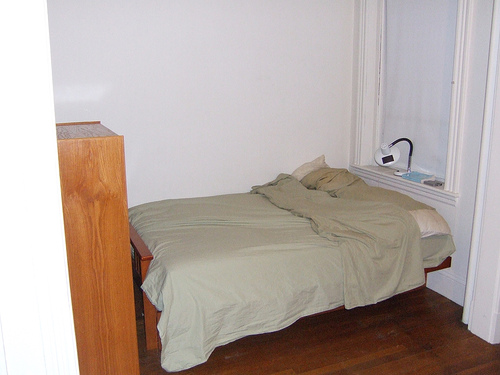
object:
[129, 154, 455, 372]
bed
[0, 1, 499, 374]
room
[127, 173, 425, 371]
blanket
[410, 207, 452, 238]
pillow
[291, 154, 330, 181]
pillow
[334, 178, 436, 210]
pillow case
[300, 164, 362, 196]
pillow case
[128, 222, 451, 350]
bed frame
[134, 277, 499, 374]
floor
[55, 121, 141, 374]
shelf stand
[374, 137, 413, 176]
lamp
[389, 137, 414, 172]
gooseneck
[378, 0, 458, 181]
shade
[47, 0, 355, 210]
wall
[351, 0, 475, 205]
window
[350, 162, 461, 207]
window sill